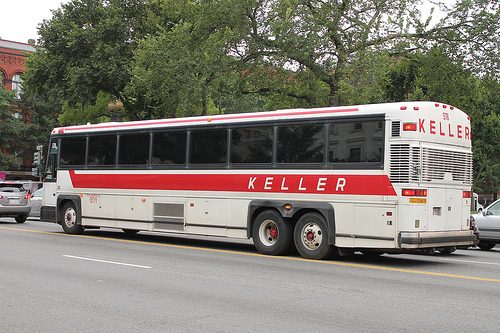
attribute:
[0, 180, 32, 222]
car — silver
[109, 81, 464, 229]
bus — red, white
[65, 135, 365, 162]
window — reflective, black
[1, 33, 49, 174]
building — red, brick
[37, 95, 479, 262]
bus — red and white, white, obeying, law, long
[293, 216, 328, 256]
wheel — black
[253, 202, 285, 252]
wheel — black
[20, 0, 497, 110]
trees — large ,  green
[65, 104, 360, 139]
stripe — red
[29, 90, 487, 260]
silver spoon — red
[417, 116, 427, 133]
k — red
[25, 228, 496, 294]
line — yellow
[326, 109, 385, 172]
window — black, reflective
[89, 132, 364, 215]
passenger windows — in row, passenger's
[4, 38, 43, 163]
brick building — red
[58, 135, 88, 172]
window — square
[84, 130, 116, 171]
window — square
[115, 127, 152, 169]
window — square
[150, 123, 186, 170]
window — square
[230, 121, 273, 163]
window — square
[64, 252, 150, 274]
line — white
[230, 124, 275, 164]
window — reflective, black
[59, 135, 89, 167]
window — reflective, black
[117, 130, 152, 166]
window — reflective, black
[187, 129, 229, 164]
window — reflective, black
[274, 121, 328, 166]
window — reflective, black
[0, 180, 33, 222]
vehicle — silver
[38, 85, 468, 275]
bus — white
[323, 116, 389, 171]
window — black, reflective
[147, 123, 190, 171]
window — black, reflective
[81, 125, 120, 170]
window — black, reflective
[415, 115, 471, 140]
letters — red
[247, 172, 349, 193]
company — KELLER